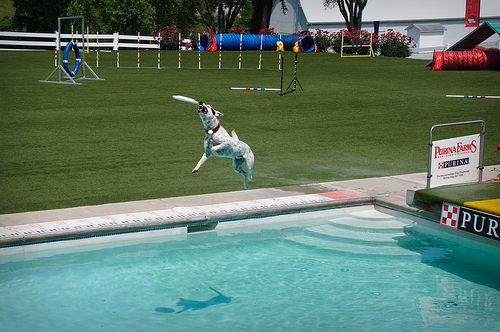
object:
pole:
[238, 31, 243, 68]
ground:
[189, 72, 233, 87]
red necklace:
[204, 125, 221, 137]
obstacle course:
[37, 12, 500, 96]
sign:
[434, 199, 459, 229]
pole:
[95, 30, 102, 67]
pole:
[196, 31, 202, 70]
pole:
[258, 30, 265, 67]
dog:
[191, 100, 257, 190]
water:
[2, 264, 497, 329]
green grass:
[1, 148, 57, 196]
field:
[302, 55, 422, 86]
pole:
[135, 30, 142, 68]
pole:
[444, 92, 499, 98]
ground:
[309, 98, 496, 122]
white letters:
[457, 209, 497, 241]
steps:
[286, 202, 438, 264]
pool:
[0, 198, 499, 330]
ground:
[2, 48, 39, 82]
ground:
[319, 123, 393, 163]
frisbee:
[171, 94, 203, 105]